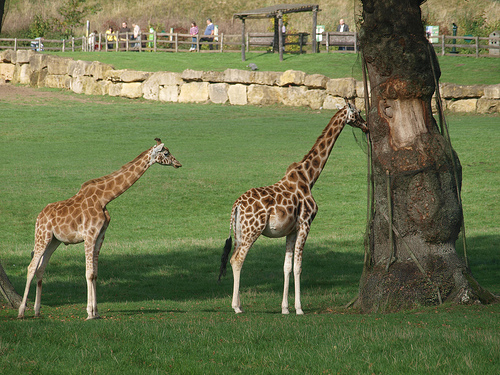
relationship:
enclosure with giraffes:
[0, 82, 500, 375] [24, 97, 368, 321]